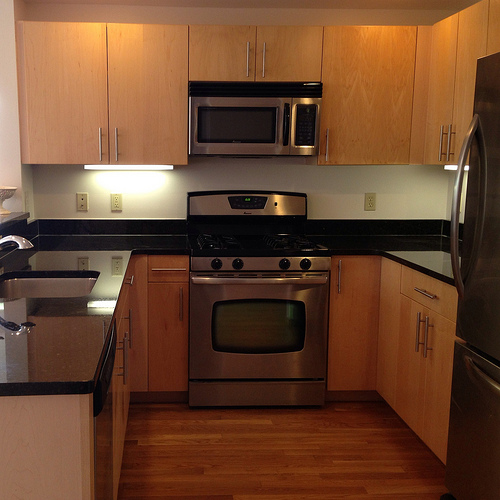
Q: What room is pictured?
A: Kitchen.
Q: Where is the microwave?
A: In the cabinets.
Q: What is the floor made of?
A: Wood.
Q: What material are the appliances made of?
A: Stainless steel.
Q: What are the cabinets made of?
A: Wood.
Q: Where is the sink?
A: In the countertop.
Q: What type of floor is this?
A: Hardwood.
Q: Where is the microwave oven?
A: Above the stove.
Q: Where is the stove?
A: Below the microwave oven.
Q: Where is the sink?
A: Left of the stove.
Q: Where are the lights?
A: Under the cabinets.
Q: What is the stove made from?
A: Stainless steel.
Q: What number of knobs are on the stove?
A: 4.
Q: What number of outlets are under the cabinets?
A: 3.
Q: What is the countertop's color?
A: Black.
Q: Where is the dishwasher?
A: Under the counter.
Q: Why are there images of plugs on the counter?
A: Reflections.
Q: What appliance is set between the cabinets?
A: Microwave.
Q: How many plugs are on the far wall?
A: 3.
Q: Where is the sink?
A: To the left.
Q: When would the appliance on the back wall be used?
A: Cooking.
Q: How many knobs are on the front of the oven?
A: 4.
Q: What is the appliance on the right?
A: Refrigerator.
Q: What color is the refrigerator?
A: Black.